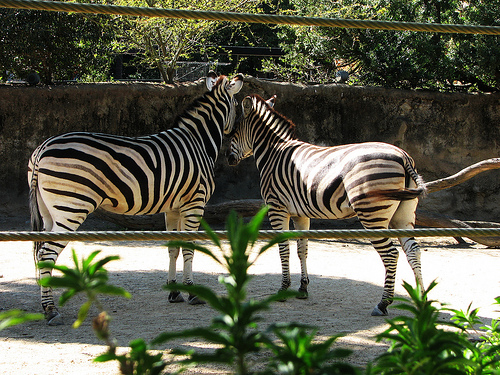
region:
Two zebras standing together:
[21, 70, 441, 328]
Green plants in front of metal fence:
[6, 201, 498, 371]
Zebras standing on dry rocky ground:
[5, 72, 499, 373]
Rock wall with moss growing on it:
[4, 75, 499, 226]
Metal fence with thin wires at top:
[11, 39, 318, 79]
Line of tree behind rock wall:
[4, 3, 496, 224]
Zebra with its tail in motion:
[225, 92, 437, 319]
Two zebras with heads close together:
[19, 64, 431, 326]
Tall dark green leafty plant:
[35, 249, 187, 374]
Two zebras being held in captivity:
[6, 47, 438, 323]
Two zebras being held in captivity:
[13, 68, 446, 313]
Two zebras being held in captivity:
[12, 54, 484, 309]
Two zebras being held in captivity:
[49, 76, 416, 281]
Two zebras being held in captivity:
[10, 72, 464, 289]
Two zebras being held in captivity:
[30, 63, 444, 286]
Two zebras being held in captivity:
[1, 74, 467, 285]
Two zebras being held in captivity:
[133, 65, 378, 292]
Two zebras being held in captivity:
[115, 62, 328, 290]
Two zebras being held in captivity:
[104, 69, 351, 318]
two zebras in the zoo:
[6, 31, 460, 328]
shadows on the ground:
[11, 262, 459, 361]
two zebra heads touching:
[172, 70, 289, 180]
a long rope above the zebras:
[71, 1, 493, 82]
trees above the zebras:
[0, 0, 497, 96]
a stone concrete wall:
[1, 78, 498, 230]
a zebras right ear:
[217, 70, 249, 98]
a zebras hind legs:
[320, 216, 435, 338]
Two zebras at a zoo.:
[21, 73, 433, 328]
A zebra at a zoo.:
[226, 94, 434, 317]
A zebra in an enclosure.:
[23, 70, 244, 321]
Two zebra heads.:
[200, 66, 275, 161]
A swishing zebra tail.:
[361, 150, 427, 205]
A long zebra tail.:
[25, 135, 52, 291]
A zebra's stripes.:
[48, 135, 203, 205]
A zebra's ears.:
[203, 70, 246, 96]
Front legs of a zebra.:
[265, 197, 317, 303]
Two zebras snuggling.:
[187, 74, 294, 173]